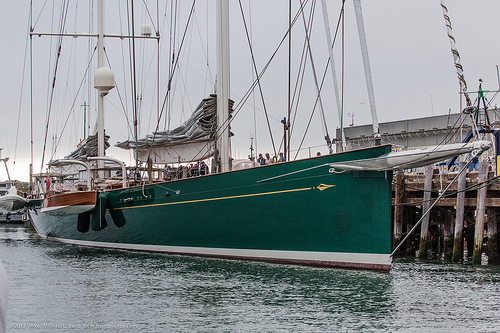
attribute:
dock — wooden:
[397, 163, 498, 258]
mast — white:
[73, 6, 250, 186]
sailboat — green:
[24, 142, 404, 270]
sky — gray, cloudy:
[5, 5, 495, 189]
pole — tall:
[212, 0, 231, 172]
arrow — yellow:
[103, 180, 333, 217]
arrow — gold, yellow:
[102, 177, 338, 216]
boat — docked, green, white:
[22, 136, 496, 276]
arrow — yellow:
[103, 180, 336, 212]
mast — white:
[213, 1, 230, 172]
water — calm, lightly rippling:
[4, 220, 492, 330]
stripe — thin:
[100, 180, 336, 213]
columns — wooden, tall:
[413, 151, 484, 256]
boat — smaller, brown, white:
[40, 178, 100, 215]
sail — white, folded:
[147, 120, 213, 158]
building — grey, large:
[394, 120, 457, 144]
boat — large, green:
[39, 170, 397, 275]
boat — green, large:
[50, 152, 396, 276]